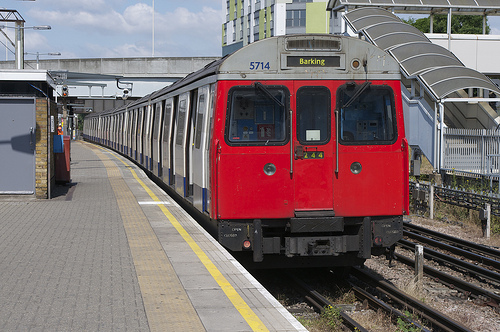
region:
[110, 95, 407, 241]
red and grey train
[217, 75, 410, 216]
red doors on train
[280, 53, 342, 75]
green location on train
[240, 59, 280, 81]
blue numbers on train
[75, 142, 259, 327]
yellow line on platform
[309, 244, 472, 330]
brown tracks under train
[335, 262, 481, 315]
brown grass under train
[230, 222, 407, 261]
red lights on train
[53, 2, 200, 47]
blue and white sky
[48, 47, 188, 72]
grey bridge over train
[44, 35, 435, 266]
this is a train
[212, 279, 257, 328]
a line on the road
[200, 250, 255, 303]
a line on the road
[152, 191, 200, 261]
a line on the road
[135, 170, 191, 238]
a line on the road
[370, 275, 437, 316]
this sis a railway line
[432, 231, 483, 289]
this sis a railway line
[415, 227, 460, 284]
this sis a railway line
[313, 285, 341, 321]
this sis a railway line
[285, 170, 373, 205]
the train is red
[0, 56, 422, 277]
train at the station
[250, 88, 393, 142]
windows on the train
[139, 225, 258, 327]
safety line on platform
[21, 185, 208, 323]
platform for the train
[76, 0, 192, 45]
clouds in the sky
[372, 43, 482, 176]
stairs at the station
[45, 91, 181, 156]
side of the train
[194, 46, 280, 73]
number of the train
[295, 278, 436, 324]
track for the train